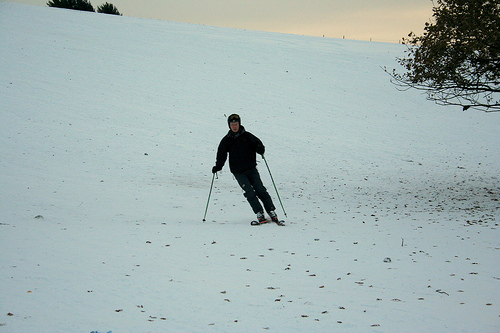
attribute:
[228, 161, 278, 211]
pants — gray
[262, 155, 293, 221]
poles — ski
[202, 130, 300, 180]
jacket — black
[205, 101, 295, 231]
skier — in the picture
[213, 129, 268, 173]
coat — black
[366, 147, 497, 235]
shadow — light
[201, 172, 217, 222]
pole — ski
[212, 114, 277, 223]
man — skiing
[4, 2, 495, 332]
snow — white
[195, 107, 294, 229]
skier — in the picture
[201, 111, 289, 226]
skier — in the picture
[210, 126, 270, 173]
jacket — ski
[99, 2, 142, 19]
tree — green